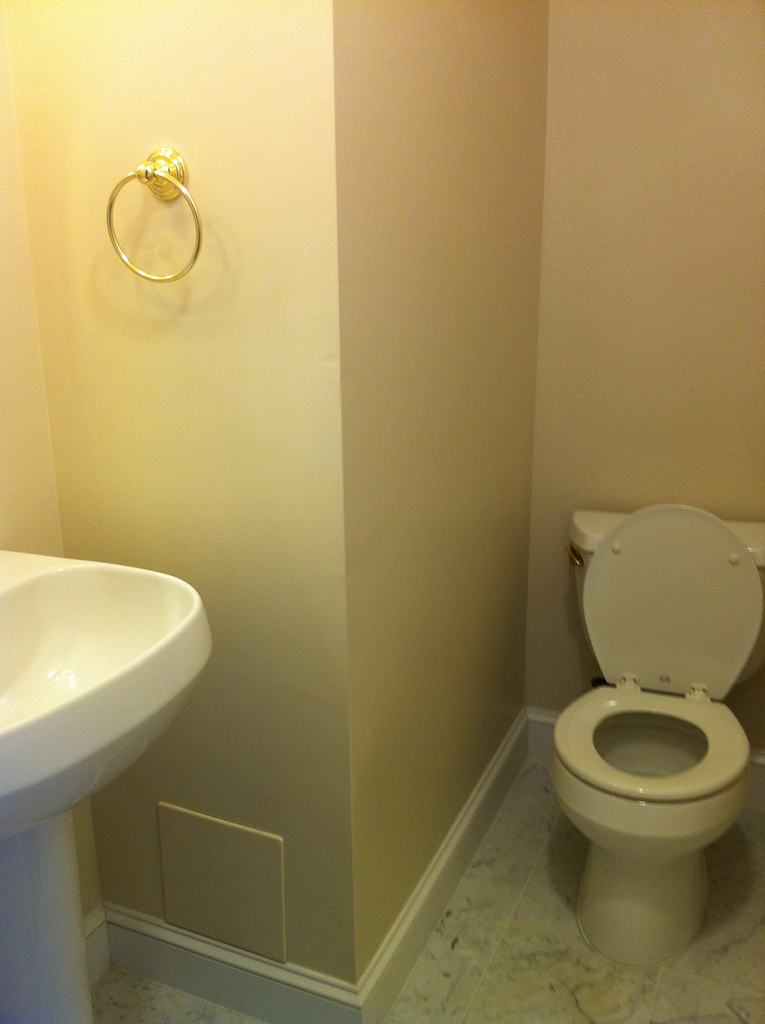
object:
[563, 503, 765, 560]
tank lid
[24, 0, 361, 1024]
beige wall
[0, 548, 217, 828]
sink top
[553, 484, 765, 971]
toilet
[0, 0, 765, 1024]
bathroom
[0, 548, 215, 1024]
sink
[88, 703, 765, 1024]
tile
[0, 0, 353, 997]
wall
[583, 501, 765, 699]
toilet lid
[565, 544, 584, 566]
fush lever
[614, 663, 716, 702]
hinges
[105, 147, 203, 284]
gold holder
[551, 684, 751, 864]
seat